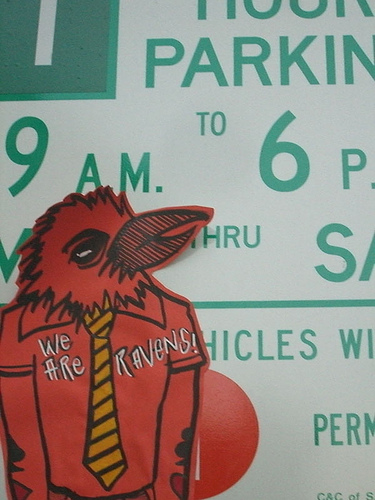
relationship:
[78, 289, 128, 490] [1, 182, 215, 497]
tie on bird mascot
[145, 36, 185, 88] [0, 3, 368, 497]
letter on sign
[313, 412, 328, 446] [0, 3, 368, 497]
letter on sign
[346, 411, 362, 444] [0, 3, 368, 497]
letter on sign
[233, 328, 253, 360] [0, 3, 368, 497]
letter on sign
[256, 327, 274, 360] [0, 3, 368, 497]
letter on sign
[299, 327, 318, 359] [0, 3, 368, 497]
letter on sign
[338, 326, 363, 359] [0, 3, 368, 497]
letter on sign